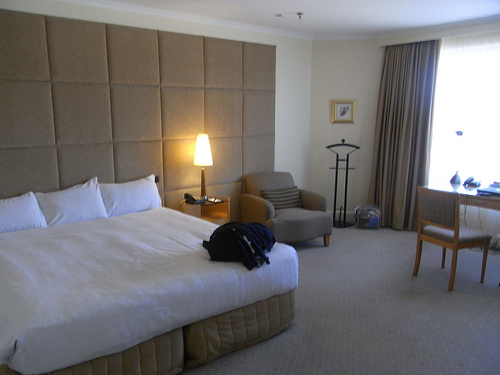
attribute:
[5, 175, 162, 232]
pillows — white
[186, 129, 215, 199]
lamp — on, brown, lit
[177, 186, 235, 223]
table — brown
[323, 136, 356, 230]
clothes stand — black, metal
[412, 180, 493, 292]
chair — wood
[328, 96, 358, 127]
picture — hanging, gold, square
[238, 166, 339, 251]
chair — brown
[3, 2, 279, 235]
wall panels — brown, gray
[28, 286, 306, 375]
bedskirt — tan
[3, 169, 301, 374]
bed — king-sized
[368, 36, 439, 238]
curtains — hanging, brown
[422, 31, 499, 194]
window — sunny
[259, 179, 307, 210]
pillow — rectangular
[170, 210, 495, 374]
carpet — gray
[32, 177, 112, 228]
pillow — white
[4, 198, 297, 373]
blanket — white